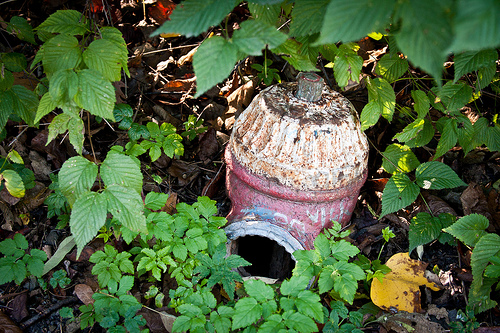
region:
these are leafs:
[58, 159, 155, 253]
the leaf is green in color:
[62, 164, 149, 232]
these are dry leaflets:
[138, 41, 183, 103]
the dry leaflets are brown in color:
[135, 55, 190, 115]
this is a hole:
[223, 224, 303, 300]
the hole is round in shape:
[216, 224, 301, 294]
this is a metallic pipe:
[217, 69, 357, 282]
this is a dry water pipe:
[217, 77, 364, 287]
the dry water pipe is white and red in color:
[210, 80, 368, 282]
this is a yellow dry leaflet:
[370, 261, 435, 313]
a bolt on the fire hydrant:
[295, 71, 324, 102]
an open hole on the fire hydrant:
[213, 219, 309, 290]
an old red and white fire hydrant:
[212, 70, 370, 292]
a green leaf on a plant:
[191, 34, 237, 99]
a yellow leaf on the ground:
[366, 250, 447, 315]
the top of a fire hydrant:
[225, 79, 370, 193]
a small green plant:
[0, 228, 49, 289]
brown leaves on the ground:
[106, 0, 248, 201]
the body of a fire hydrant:
[217, 145, 369, 289]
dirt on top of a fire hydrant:
[263, 79, 353, 126]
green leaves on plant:
[21, 5, 147, 150]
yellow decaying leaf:
[353, 230, 468, 331]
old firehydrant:
[213, 67, 384, 302]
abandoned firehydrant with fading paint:
[183, 15, 496, 320]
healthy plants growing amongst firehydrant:
[92, 41, 447, 329]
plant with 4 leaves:
[55, 152, 146, 242]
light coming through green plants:
[237, 5, 497, 185]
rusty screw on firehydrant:
[290, 63, 330, 118]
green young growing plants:
[107, 190, 357, 325]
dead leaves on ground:
[122, 6, 237, 137]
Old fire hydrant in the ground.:
[225, 67, 371, 287]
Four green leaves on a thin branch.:
[59, 146, 147, 258]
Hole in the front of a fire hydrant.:
[232, 230, 294, 285]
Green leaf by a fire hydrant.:
[375, 170, 417, 222]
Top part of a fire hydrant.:
[293, 68, 325, 103]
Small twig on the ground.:
[17, 294, 77, 327]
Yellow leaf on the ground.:
[367, 252, 442, 315]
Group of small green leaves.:
[133, 120, 185, 160]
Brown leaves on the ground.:
[135, 60, 187, 119]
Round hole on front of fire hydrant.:
[217, 217, 305, 301]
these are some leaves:
[79, 162, 164, 282]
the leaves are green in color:
[78, 162, 132, 221]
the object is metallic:
[249, 98, 324, 210]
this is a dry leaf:
[385, 268, 420, 308]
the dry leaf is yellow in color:
[389, 261, 414, 306]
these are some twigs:
[139, 18, 170, 115]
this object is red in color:
[243, 185, 339, 221]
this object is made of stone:
[286, 106, 323, 161]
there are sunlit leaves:
[348, 25, 405, 90]